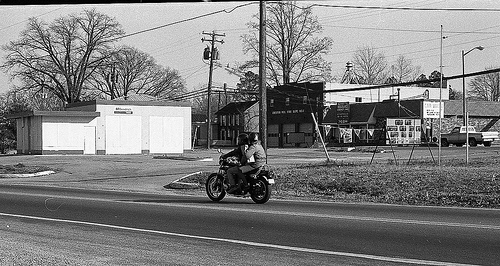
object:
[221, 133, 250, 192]
man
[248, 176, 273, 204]
wheel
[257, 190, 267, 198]
part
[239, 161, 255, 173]
shorts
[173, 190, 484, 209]
edge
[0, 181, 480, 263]
road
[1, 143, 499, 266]
ground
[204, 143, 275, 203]
motorcycle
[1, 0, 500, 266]
town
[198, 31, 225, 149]
utility pole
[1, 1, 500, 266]
picture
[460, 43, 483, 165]
street light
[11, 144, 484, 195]
road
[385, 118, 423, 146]
sign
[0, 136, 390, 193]
parking lot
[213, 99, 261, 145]
buildings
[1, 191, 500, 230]
line